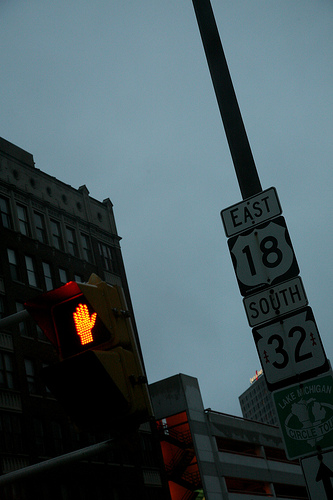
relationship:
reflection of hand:
[49, 280, 83, 310] [72, 304, 99, 346]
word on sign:
[299, 383, 333, 399] [270, 372, 332, 458]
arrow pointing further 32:
[262, 347, 274, 370] [270, 324, 310, 371]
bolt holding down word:
[275, 307, 283, 315] [249, 285, 300, 321]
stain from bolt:
[252, 229, 262, 247] [255, 230, 258, 235]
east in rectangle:
[231, 194, 273, 226] [222, 185, 283, 236]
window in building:
[24, 255, 38, 287] [0, 139, 149, 444]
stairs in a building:
[156, 411, 204, 499] [149, 374, 326, 500]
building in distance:
[0, 132, 300, 499] [0, 0, 327, 428]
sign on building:
[246, 365, 264, 389] [0, 132, 300, 499]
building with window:
[0, 139, 149, 444] [24, 255, 38, 287]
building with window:
[0, 139, 149, 444] [79, 234, 93, 261]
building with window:
[0, 139, 149, 444] [20, 207, 28, 239]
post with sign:
[193, 0, 264, 203] [221, 187, 330, 499]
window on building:
[24, 255, 38, 287] [0, 139, 149, 444]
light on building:
[72, 304, 99, 346] [0, 139, 149, 444]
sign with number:
[251, 306, 330, 390] [270, 324, 310, 371]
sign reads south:
[242, 276, 309, 328] [249, 285, 300, 321]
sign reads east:
[222, 186, 282, 241] [231, 194, 273, 226]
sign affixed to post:
[222, 186, 282, 241] [193, 0, 264, 203]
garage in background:
[149, 374, 326, 500] [0, 135, 332, 495]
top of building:
[1, 139, 35, 167] [0, 139, 149, 444]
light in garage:
[153, 409, 202, 499] [149, 374, 326, 500]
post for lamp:
[193, 0, 264, 203] [190, 0, 214, 6]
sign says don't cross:
[38, 285, 131, 348] [72, 304, 99, 346]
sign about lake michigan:
[270, 372, 332, 458] [280, 383, 332, 406]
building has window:
[0, 139, 149, 444] [24, 255, 38, 287]